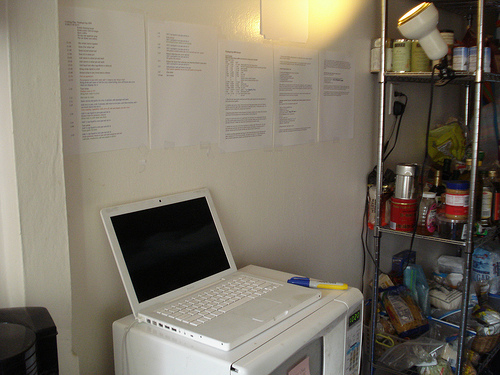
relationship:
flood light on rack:
[393, 2, 451, 63] [364, 0, 499, 373]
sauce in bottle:
[418, 220, 439, 234] [415, 189, 439, 237]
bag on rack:
[376, 282, 431, 338] [364, 0, 499, 373]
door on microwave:
[232, 299, 346, 373] [111, 264, 364, 374]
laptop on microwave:
[100, 187, 323, 350] [111, 264, 364, 374]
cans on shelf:
[451, 43, 492, 73] [382, 70, 498, 83]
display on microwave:
[346, 310, 361, 327] [111, 264, 364, 374]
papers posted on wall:
[61, 7, 351, 147] [2, 1, 454, 371]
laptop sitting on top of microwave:
[98, 187, 325, 353] [105, 264, 371, 374]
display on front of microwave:
[346, 309, 363, 327] [105, 264, 371, 374]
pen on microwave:
[289, 276, 349, 291] [105, 264, 371, 374]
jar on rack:
[442, 179, 470, 215] [374, 226, 495, 247]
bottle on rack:
[419, 191, 439, 234] [378, 221, 495, 247]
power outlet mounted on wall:
[388, 87, 402, 119] [2, 1, 454, 371]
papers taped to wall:
[61, 7, 351, 147] [2, 1, 454, 371]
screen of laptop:
[110, 198, 231, 304] [100, 187, 323, 350]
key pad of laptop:
[156, 270, 274, 325] [100, 187, 323, 350]